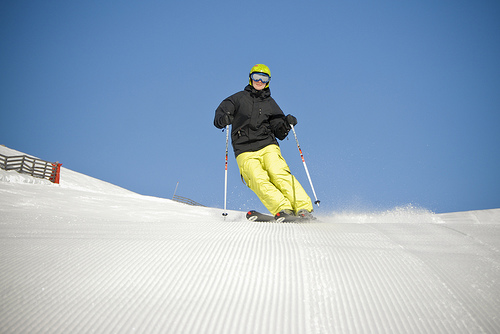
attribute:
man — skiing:
[217, 87, 327, 221]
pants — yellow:
[256, 168, 286, 196]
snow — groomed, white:
[127, 215, 220, 284]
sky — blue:
[158, 23, 251, 63]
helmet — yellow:
[251, 62, 278, 72]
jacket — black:
[242, 95, 274, 128]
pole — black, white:
[295, 142, 312, 164]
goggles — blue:
[249, 71, 278, 88]